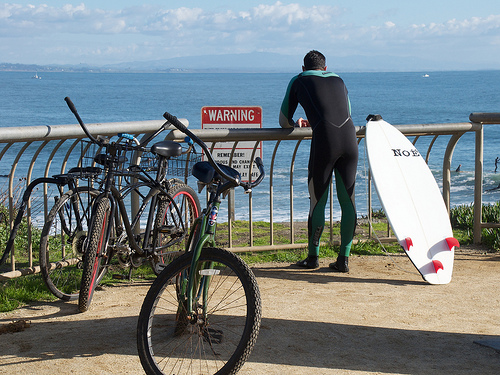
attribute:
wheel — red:
[89, 213, 113, 270]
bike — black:
[75, 117, 128, 296]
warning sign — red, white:
[200, 103, 263, 185]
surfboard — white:
[355, 109, 467, 301]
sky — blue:
[113, 14, 478, 47]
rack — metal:
[2, 110, 51, 285]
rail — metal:
[1, 119, 484, 279]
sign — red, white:
[195, 103, 270, 186]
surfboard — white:
[362, 109, 467, 291]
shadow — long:
[1, 307, 498, 372]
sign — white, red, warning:
[199, 105, 263, 185]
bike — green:
[128, 109, 317, 374]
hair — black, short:
[302, 47, 324, 67]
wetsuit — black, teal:
[279, 69, 359, 258]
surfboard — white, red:
[366, 111, 463, 286]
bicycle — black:
[141, 103, 273, 373]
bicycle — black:
[55, 99, 205, 311]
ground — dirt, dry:
[0, 245, 499, 373]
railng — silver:
[201, 116, 452, 167]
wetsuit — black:
[275, 70, 362, 274]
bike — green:
[139, 151, 260, 288]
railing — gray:
[71, 103, 496, 255]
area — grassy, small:
[452, 203, 476, 227]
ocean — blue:
[2, 68, 499, 236]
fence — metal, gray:
[0, 110, 498, 286]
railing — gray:
[3, 120, 489, 249]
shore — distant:
[1, 60, 477, 70]